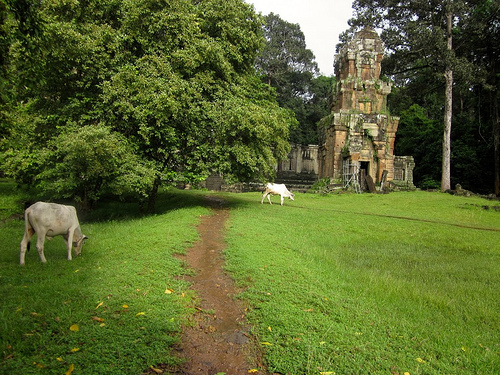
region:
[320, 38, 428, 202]
Abandoned mason structure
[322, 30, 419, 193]
Moss covered abandoned stone structure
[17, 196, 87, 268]
white cow grazing green grass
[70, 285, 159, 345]
yellow leaves amidst green grass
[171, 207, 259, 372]
a worn dirt path through green grass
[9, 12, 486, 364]
cows grazing short green grass near an old stone structure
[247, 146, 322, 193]
Old stone steps leading to a building beyond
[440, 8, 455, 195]
light colored trunk of a tall tree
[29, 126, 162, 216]
low green shrubbery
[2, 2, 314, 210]
green wooded area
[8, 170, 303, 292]
two pale divided by a thin road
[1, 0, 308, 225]
an enormous tree on the left side of the road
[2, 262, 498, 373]
yellow leaves, not too many, @ front of lovely lawn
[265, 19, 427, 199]
decaying amazing building that looks like something between an aztec+buddhist shrine in the english countryside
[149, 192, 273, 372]
path is muddy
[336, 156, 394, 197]
door is open, it is unclear if it -can- still close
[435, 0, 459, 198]
a very tall thin tree trunk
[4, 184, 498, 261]
the shadow of an enormous tree joins a long shadowed line of something, somewhere, but here invisible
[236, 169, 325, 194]
steps, although not many lead to the monument, to the back of the building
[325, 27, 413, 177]
moss, leaves, vines, ivy, cover a stone wonder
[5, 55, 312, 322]
Cows in a field.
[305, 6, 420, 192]
A temple made of stone.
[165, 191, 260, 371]
A dirt path through the field.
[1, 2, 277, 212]
A large tree next to the dirt path.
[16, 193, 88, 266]
The cow is white.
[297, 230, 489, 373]
The grass is green.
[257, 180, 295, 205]
Another white cow in the distance.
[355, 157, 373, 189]
The entrance to the temple.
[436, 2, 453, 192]
The trunk of a tree.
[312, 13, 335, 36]
The sky is overcast.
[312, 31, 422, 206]
Building in a field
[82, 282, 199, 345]
Leaves laying on the grass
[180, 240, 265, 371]
Dirt path going through the grass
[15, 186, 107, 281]
Cow grazing on the grass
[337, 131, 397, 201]
Front door on the building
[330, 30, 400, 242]
The building is made of rock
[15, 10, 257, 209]
Large tree growing in the field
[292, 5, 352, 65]
The sky is cloudy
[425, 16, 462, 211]
Tall tree in background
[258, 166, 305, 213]
The cow is looking at the ground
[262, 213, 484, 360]
The grass is very green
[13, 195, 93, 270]
A cow is eating the grass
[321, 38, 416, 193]
A tall building made of brick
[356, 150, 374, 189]
The opening of the tall building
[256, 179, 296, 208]
A cow is walking across the grass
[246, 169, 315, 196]
The stack of stairs to a building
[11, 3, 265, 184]
The tree is tall with green leaves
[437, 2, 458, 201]
The tree trunk is very tall and grey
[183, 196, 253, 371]
The middle of the grass has a mud track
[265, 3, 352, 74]
It is daytime and the sky is clear